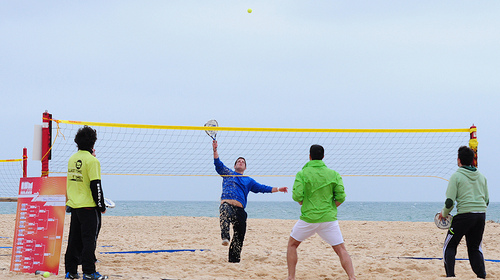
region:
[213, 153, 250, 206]
man wears blue shirt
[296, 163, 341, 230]
man wears green jacket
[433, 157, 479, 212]
man wears green shirt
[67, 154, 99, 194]
man wears yellow and black shirt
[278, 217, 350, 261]
man wears white shorts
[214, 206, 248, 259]
man wears black pants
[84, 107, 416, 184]
yellow net between people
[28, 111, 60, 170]
red and white pole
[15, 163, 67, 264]
scoreboard left of people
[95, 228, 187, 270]
blue boundary marker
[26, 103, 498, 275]
people playing tennis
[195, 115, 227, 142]
a black tennis racket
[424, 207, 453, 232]
a dog's right rear paw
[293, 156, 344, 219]
a lime green jacket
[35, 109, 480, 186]
a yellow tennis net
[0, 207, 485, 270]
a sandy beach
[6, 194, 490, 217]
a body of water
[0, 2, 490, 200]
a grey cloudy sky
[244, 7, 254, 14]
a yellow tennis ball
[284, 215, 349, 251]
a pair of white men's shorts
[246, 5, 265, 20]
a ball in the air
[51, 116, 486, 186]
A yellow volleyball net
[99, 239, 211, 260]
blue line in the sand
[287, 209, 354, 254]
white pair of shorts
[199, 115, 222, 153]
a man holding a racquet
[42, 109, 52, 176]
a pole for the volley net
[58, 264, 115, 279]
blue and black shoes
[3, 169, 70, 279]
a sign in the sand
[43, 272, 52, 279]
a ball on the ground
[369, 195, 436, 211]
the ocean waves in the distance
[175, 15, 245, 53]
part of the sky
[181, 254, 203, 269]
part of some sand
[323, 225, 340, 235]
part of a short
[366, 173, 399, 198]
edge of a net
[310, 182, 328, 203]
part of a shirt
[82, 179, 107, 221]
part of a sleeve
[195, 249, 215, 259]
part of a beach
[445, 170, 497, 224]
person wears green shirt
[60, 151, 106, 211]
man wears yellow shirt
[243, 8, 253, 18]
yellow ball in air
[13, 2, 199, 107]
sky is light blue with few clouds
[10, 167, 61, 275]
red and yellow standings board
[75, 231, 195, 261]
blue border on sand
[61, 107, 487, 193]
yellow net between players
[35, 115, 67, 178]
yellow net on red pole